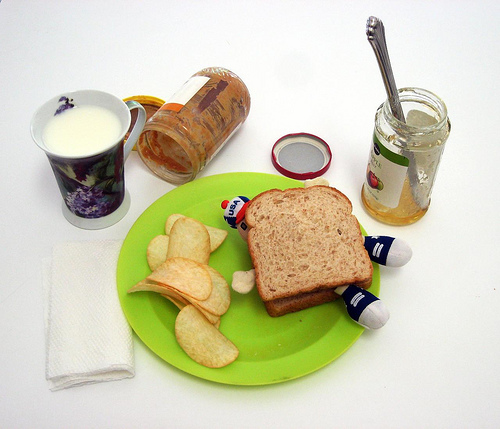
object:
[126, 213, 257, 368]
chips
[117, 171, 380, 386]
plate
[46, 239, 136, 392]
napkin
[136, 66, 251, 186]
jar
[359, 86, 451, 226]
jar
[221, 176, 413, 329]
doll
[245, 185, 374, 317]
bread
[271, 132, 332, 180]
lid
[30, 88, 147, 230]
mug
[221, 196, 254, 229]
hat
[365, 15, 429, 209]
knife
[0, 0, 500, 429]
table